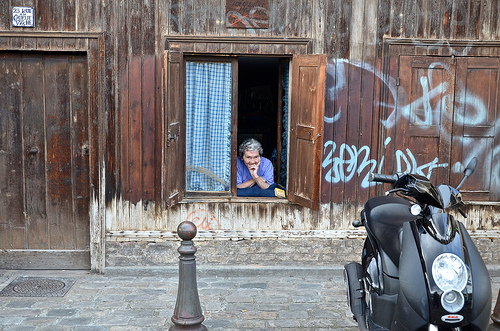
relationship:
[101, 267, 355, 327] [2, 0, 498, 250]
ground near building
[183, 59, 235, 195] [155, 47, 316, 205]
curtain on window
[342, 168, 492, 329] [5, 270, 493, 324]
scooter on sidewalk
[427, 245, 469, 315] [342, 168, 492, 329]
lights on scooter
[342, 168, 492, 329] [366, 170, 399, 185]
scooter has grip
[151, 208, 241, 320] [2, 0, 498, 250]
pole outside building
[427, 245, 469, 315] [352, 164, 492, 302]
lights of a vehicle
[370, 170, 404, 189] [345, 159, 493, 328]
handlebar on bike